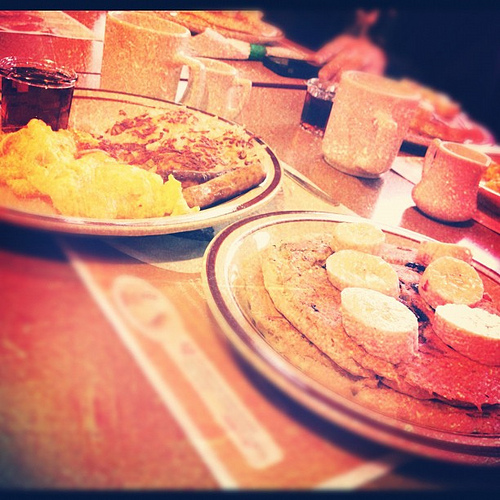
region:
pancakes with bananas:
[230, 199, 496, 384]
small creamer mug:
[421, 117, 492, 234]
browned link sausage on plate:
[170, 160, 285, 202]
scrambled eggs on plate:
[2, 111, 197, 249]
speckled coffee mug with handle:
[325, 64, 409, 194]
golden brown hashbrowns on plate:
[92, 91, 265, 180]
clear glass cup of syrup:
[290, 63, 352, 146]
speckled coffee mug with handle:
[97, 9, 207, 109]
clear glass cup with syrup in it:
[0, 46, 92, 130]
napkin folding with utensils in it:
[192, 19, 327, 76]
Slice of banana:
[336, 278, 431, 360]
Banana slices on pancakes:
[227, 241, 496, 426]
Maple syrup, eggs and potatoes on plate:
[1, 81, 265, 236]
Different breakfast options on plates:
[1, 5, 493, 494]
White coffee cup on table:
[304, 72, 433, 174]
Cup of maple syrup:
[0, 53, 105, 133]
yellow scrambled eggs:
[0, 120, 192, 252]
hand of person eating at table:
[280, 14, 393, 89]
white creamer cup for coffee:
[398, 141, 498, 234]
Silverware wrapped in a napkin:
[186, 19, 313, 89]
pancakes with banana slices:
[248, 214, 498, 392]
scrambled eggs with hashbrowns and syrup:
[2, 53, 264, 199]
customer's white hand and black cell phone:
[258, 46, 370, 73]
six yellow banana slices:
[333, 223, 498, 350]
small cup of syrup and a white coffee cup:
[310, 70, 414, 180]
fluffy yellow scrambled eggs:
[5, 129, 175, 216]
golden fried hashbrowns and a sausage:
[104, 103, 259, 181]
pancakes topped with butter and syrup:
[402, 75, 488, 145]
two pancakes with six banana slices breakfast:
[217, 212, 499, 428]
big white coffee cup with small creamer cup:
[106, 11, 257, 111]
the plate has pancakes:
[257, 238, 497, 445]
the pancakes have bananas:
[336, 215, 498, 385]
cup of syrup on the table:
[412, 117, 489, 229]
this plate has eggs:
[5, 130, 191, 228]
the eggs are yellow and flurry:
[3, 127, 198, 221]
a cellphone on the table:
[255, 55, 342, 84]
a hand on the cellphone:
[281, 45, 371, 83]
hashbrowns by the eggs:
[80, 112, 261, 173]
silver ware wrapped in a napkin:
[183, 25, 325, 68]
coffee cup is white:
[311, 70, 412, 192]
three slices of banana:
[326, 219, 424, 362]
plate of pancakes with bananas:
[202, 207, 498, 477]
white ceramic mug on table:
[322, 59, 417, 196]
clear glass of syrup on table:
[292, 73, 337, 139]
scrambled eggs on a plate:
[3, 118, 203, 242]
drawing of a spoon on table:
[92, 269, 288, 487]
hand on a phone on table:
[261, 32, 391, 93]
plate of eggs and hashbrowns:
[7, 54, 280, 250]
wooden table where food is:
[3, 279, 113, 493]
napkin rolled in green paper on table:
[184, 29, 314, 67]